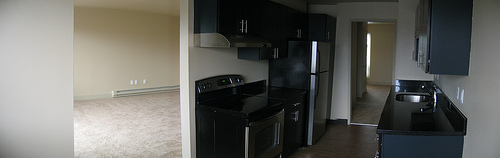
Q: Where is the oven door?
A: Under the stove.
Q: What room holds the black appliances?
A: The kitchen.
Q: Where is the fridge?
A: Across from the sink.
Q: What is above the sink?
A: Cabinets.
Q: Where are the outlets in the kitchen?
A: Above the counter near the sink.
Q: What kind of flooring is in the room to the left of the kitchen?
A: Carpet.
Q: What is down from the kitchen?
A: Hall.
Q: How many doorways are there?
A: Two.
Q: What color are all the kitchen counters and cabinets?
A: Black.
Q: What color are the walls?
A: White.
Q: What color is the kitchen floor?
A: Brown.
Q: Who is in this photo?
A: Nobody.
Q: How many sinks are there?
A: One.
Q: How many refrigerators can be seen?
A: One.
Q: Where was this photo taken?
A: The kitchen.